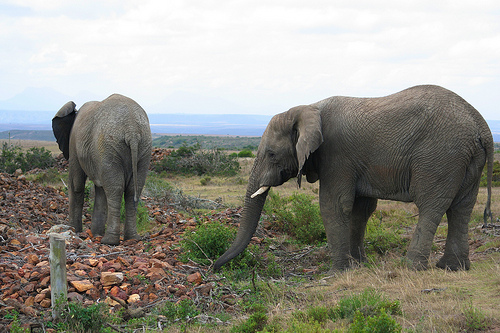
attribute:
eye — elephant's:
[268, 147, 279, 162]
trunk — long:
[202, 179, 272, 279]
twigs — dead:
[145, 280, 233, 318]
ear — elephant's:
[298, 107, 329, 170]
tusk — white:
[249, 186, 268, 199]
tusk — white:
[250, 182, 269, 199]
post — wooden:
[41, 230, 69, 320]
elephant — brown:
[43, 90, 153, 242]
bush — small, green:
[195, 215, 236, 259]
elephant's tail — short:
[124, 134, 141, 206]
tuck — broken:
[242, 190, 273, 201]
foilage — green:
[153, 144, 241, 176]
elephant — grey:
[241, 100, 433, 237]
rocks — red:
[0, 172, 252, 309]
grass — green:
[341, 265, 498, 330]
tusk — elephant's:
[247, 184, 265, 199]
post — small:
[30, 230, 84, 327]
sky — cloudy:
[19, 8, 485, 115]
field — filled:
[4, 129, 496, 332]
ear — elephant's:
[290, 104, 327, 190]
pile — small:
[475, 220, 498, 233]